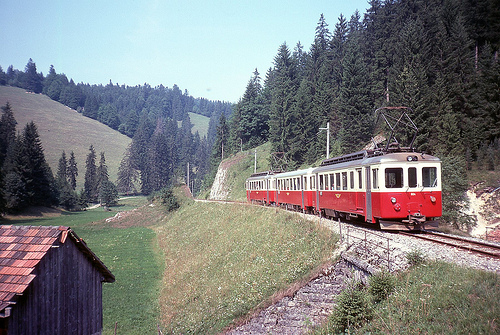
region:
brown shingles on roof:
[1, 220, 71, 332]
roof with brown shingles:
[1, 217, 57, 325]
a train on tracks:
[239, 146, 450, 230]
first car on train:
[314, 155, 445, 233]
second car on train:
[273, 168, 322, 215]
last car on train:
[239, 162, 276, 202]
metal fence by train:
[342, 217, 397, 273]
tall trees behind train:
[0, 59, 220, 211]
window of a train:
[385, 167, 408, 190]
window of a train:
[406, 165, 421, 188]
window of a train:
[419, 158, 440, 186]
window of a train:
[369, 163, 384, 186]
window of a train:
[350, 163, 361, 190]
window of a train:
[339, 163, 351, 192]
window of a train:
[328, 172, 343, 190]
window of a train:
[272, 173, 289, 193]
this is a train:
[214, 144, 468, 256]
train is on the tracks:
[195, 97, 496, 272]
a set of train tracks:
[414, 219, 496, 291]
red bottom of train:
[254, 185, 434, 230]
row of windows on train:
[243, 168, 368, 204]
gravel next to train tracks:
[377, 233, 499, 290]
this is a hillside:
[118, 174, 432, 333]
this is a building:
[0, 204, 128, 332]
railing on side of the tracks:
[330, 204, 405, 279]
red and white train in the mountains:
[246, 148, 440, 230]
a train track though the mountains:
[192, 195, 498, 262]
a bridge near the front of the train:
[337, 225, 409, 270]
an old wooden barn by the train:
[2, 224, 117, 331]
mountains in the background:
[0, 74, 229, 191]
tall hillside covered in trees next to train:
[217, 1, 494, 164]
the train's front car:
[312, 144, 440, 231]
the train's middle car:
[270, 165, 312, 212]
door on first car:
[365, 165, 374, 222]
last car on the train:
[246, 169, 270, 203]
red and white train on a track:
[211, 108, 452, 240]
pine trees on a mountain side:
[88, 70, 240, 200]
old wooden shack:
[11, 216, 170, 323]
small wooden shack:
[8, 215, 153, 326]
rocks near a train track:
[304, 217, 453, 302]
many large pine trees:
[111, 82, 223, 173]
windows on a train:
[383, 167, 435, 188]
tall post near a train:
[316, 120, 332, 157]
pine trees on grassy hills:
[0, 0, 498, 212]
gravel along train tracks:
[385, 232, 498, 264]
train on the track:
[244, 138, 459, 237]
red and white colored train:
[236, 144, 449, 237]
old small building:
[1, 215, 122, 334]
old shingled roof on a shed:
[2, 220, 119, 319]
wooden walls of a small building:
[13, 231, 113, 333]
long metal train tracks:
[192, 194, 497, 269]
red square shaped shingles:
[1, 222, 119, 310]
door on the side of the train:
[363, 160, 375, 222]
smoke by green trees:
[171, 103, 228, 206]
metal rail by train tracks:
[340, 215, 457, 267]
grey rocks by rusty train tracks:
[429, 235, 486, 252]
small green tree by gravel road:
[87, 177, 122, 214]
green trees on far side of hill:
[12, 54, 157, 146]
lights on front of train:
[383, 152, 446, 220]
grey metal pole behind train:
[312, 113, 341, 190]